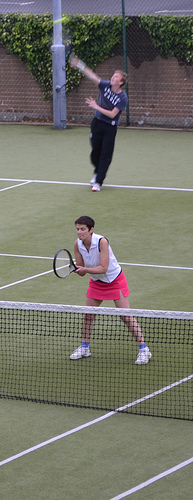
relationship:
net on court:
[0, 298, 191, 422] [0, 123, 193, 499]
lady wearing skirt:
[70, 215, 153, 366] [86, 268, 129, 299]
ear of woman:
[88, 224, 94, 232] [62, 221, 148, 353]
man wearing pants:
[84, 70, 127, 192] [90, 118, 116, 182]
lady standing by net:
[70, 215, 153, 366] [0, 298, 191, 422]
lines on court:
[0, 176, 193, 465] [66, 134, 193, 396]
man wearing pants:
[64, 50, 122, 191] [83, 119, 117, 183]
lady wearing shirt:
[70, 215, 153, 366] [52, 218, 152, 367]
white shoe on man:
[86, 165, 97, 187] [44, 33, 124, 200]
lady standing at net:
[57, 215, 147, 314] [3, 296, 191, 392]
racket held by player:
[53, 248, 79, 279] [51, 216, 152, 368]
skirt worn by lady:
[86, 268, 129, 299] [70, 215, 153, 366]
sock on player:
[136, 340, 146, 349] [51, 216, 152, 368]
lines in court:
[20, 250, 59, 284] [11, 161, 190, 497]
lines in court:
[0, 176, 193, 465] [8, 118, 154, 498]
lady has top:
[70, 215, 153, 366] [64, 232, 129, 286]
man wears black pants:
[84, 70, 127, 192] [87, 118, 116, 184]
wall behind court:
[1, 11, 190, 130] [6, 123, 173, 496]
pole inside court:
[50, 0, 65, 127] [0, 123, 193, 499]